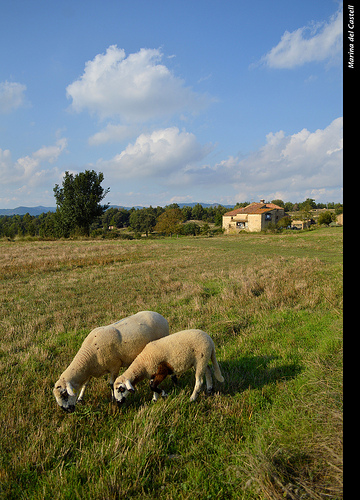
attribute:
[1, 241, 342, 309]
grass — green, brown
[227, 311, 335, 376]
grass — green, waving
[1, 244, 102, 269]
grass — brown, waving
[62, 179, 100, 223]
leaves — green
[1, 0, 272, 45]
sky — blue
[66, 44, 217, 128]
cloud — white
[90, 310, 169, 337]
wool — white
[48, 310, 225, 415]
sheep — feeding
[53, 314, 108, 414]
sheep — grazing, feeding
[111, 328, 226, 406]
sheep — feeding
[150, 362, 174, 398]
leg — brown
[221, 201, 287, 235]
house — yellow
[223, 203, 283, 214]
roof — red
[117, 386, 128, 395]
markings — black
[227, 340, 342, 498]
grass — waving, long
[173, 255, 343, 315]
grass — waving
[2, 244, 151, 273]
grass — waving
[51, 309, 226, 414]
these — sheep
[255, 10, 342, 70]
cloud — white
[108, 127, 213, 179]
cloud — white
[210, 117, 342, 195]
cloud — white